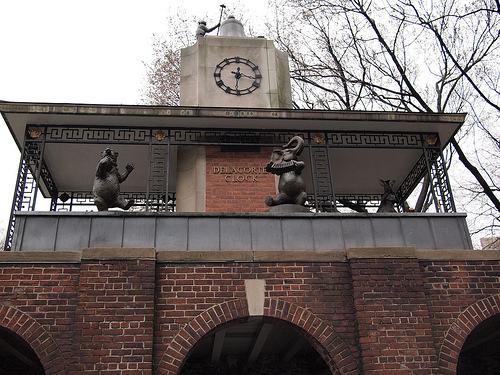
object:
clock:
[213, 56, 264, 98]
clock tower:
[0, 2, 500, 375]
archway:
[161, 294, 358, 375]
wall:
[0, 247, 500, 375]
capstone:
[245, 276, 264, 316]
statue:
[195, 19, 220, 44]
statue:
[266, 135, 310, 208]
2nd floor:
[11, 125, 474, 255]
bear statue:
[93, 145, 135, 211]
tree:
[262, 0, 500, 251]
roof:
[480, 237, 500, 251]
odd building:
[481, 236, 500, 249]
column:
[348, 248, 443, 375]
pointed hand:
[231, 70, 258, 79]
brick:
[370, 275, 388, 281]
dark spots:
[101, 275, 128, 284]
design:
[52, 127, 155, 142]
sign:
[208, 165, 271, 184]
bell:
[218, 14, 247, 37]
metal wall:
[11, 212, 474, 251]